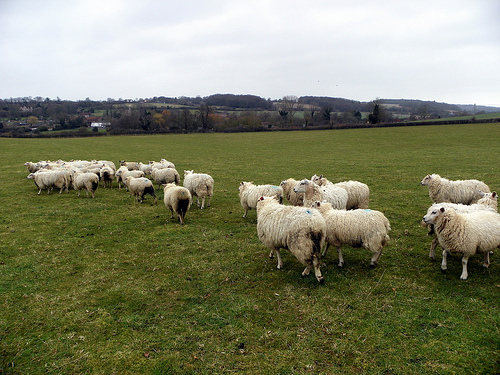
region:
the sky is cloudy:
[265, 30, 379, 62]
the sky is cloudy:
[297, 57, 417, 94]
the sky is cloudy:
[250, 22, 327, 57]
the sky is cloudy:
[270, 18, 415, 76]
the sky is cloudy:
[266, 1, 357, 71]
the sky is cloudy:
[300, 38, 402, 69]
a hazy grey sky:
[3, 3, 494, 105]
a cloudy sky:
[4, 8, 494, 100]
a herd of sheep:
[23, 153, 487, 315]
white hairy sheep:
[15, 148, 497, 303]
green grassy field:
[3, 138, 485, 374]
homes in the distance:
[2, 106, 114, 138]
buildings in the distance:
[2, 99, 132, 137]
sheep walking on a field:
[14, 131, 491, 374]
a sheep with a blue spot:
[255, 196, 337, 287]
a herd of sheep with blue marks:
[13, 147, 498, 309]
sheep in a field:
[18, 150, 498, 285]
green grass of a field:
[4, 228, 245, 372]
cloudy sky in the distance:
[12, 8, 477, 80]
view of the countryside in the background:
[13, 91, 471, 143]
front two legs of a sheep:
[438, 248, 476, 280]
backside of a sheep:
[169, 187, 196, 225]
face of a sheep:
[413, 203, 452, 232]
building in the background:
[85, 119, 118, 131]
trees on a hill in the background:
[201, 88, 275, 110]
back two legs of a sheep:
[296, 251, 336, 288]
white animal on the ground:
[216, 193, 326, 265]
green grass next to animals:
[130, 251, 231, 341]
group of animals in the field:
[20, 139, 476, 289]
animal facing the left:
[406, 201, 494, 267]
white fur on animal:
[238, 192, 313, 262]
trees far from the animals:
[157, 95, 227, 141]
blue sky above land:
[75, 25, 180, 80]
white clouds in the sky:
[180, 10, 270, 90]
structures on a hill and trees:
[5, 87, 50, 132]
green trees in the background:
[220, 86, 251, 111]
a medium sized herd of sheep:
[231, 172, 393, 287]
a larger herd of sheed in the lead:
[25, 147, 215, 229]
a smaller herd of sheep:
[419, 175, 498, 281]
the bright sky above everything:
[2, 3, 498, 103]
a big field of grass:
[2, 133, 497, 370]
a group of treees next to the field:
[4, 97, 331, 131]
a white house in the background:
[87, 118, 110, 135]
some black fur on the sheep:
[176, 198, 188, 213]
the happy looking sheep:
[419, 207, 441, 224]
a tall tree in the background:
[365, 101, 379, 125]